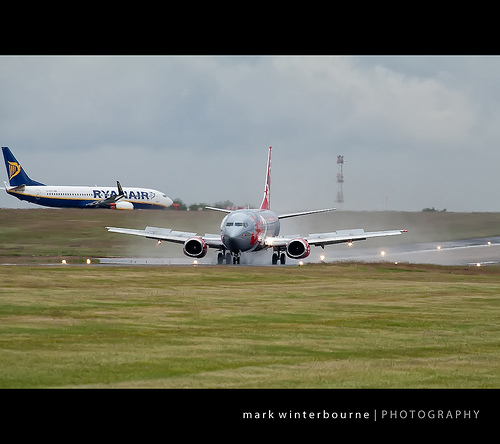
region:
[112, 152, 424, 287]
a plane about to take off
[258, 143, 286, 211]
a white and red plane's tail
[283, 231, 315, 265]
red and silver propeller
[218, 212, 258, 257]
silver cockpit of a plane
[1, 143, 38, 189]
blue tail of a plane with gold logo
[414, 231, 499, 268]
an airport runway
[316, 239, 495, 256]
illuminated lights on an airport runway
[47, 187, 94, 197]
a row of windows on a plane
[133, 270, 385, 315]
patches of dried grass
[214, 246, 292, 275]
black wheel of a plane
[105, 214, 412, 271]
Plane is on runway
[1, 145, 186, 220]
Plane is taking off or landing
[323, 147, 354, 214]
Tower is in the background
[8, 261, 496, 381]
Field is next to runway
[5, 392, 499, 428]
Credit is at bottom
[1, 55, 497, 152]
The sky is cloudy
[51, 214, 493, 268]
The runway is lit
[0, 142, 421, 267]
There are two planes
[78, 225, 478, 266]
The runway is wet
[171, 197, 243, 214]
A few trees in background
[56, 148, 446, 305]
The plane is landing.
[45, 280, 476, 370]
Some grass near the plane.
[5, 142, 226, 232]
The plane says Ryan Air.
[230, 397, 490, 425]
The white text says Mark Minterbourne Photography.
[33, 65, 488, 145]
The sky is overcast.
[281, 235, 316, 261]
A jet engine on the plane.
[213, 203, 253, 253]
The cockpit of the plane.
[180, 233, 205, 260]
Another jet engine on the plane.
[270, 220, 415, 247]
A wing on the plane.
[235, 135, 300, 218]
A rudder on the plane.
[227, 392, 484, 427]
a photographer logo in corner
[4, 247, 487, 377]
a flat grass field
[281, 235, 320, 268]
a large plane engine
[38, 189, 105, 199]
a long row of windows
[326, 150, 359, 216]
a distant metal tower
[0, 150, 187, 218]
a white and blue plane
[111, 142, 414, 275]
a silver commercial airliner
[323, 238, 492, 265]
a row of lights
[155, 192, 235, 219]
a distant group of plants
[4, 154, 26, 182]
a company logo on plane tail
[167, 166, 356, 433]
the plane is white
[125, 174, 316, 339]
the plane is white